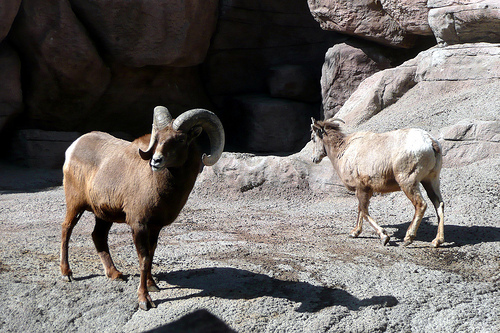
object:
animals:
[57, 104, 227, 310]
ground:
[0, 166, 498, 332]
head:
[308, 117, 339, 165]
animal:
[310, 117, 450, 251]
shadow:
[154, 266, 397, 314]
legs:
[422, 179, 445, 250]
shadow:
[233, 23, 288, 91]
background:
[0, 1, 498, 216]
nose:
[310, 154, 318, 163]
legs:
[128, 205, 160, 313]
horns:
[169, 105, 226, 166]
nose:
[150, 155, 163, 164]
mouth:
[150, 159, 164, 172]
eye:
[169, 136, 182, 149]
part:
[17, 155, 36, 173]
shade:
[3, 64, 59, 193]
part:
[39, 295, 60, 308]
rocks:
[317, 37, 395, 120]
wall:
[221, 1, 318, 153]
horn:
[326, 114, 347, 126]